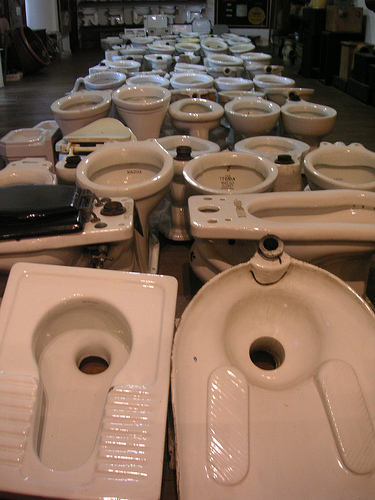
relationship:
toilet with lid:
[1, 180, 140, 267] [1, 181, 93, 236]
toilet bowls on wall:
[76, 4, 161, 28] [74, 4, 219, 55]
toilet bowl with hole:
[0, 27, 375, 500] [75, 339, 114, 374]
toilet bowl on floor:
[151, 134, 224, 242] [153, 198, 196, 282]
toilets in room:
[65, 29, 300, 98] [3, 1, 355, 495]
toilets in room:
[0, 29, 375, 500] [3, 1, 355, 495]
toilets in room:
[74, 4, 207, 28] [3, 1, 355, 495]